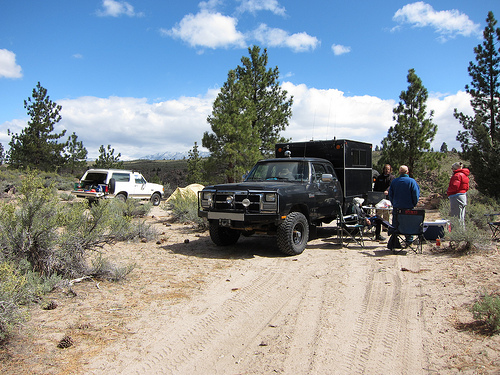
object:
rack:
[197, 187, 284, 221]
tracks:
[381, 246, 407, 373]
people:
[371, 164, 394, 232]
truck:
[194, 138, 375, 257]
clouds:
[87, 1, 145, 21]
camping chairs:
[334, 202, 365, 251]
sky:
[0, 0, 498, 163]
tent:
[164, 183, 206, 204]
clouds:
[161, 0, 353, 60]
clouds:
[0, 48, 24, 80]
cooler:
[423, 220, 451, 240]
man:
[385, 164, 419, 245]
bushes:
[0, 268, 47, 355]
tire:
[275, 211, 309, 256]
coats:
[443, 169, 474, 197]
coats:
[385, 173, 419, 208]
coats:
[371, 172, 392, 193]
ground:
[0, 191, 499, 374]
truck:
[69, 168, 165, 210]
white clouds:
[0, 82, 495, 161]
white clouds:
[389, 0, 489, 42]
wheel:
[274, 209, 311, 256]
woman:
[437, 160, 470, 237]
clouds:
[330, 41, 355, 60]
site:
[68, 137, 498, 258]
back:
[74, 168, 109, 200]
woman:
[348, 196, 395, 243]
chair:
[485, 212, 499, 245]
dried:
[31, 192, 154, 292]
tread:
[275, 225, 290, 230]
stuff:
[73, 183, 108, 193]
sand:
[84, 237, 446, 374]